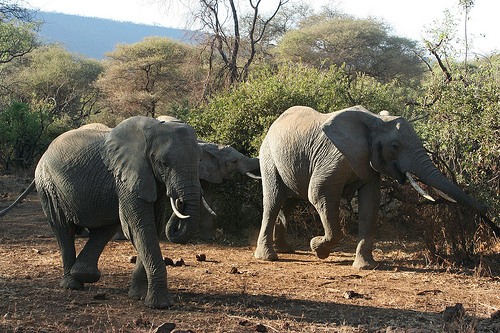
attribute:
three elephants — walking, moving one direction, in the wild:
[0, 104, 482, 310]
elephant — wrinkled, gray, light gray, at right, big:
[254, 105, 481, 270]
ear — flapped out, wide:
[319, 109, 384, 182]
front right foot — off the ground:
[306, 159, 349, 260]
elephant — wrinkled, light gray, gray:
[0, 115, 217, 308]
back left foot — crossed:
[70, 225, 118, 283]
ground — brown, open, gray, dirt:
[0, 239, 499, 333]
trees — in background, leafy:
[0, 0, 499, 243]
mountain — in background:
[0, 6, 233, 59]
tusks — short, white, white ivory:
[169, 196, 217, 218]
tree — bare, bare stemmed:
[182, 1, 288, 89]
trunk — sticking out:
[405, 142, 487, 216]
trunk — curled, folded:
[164, 171, 203, 243]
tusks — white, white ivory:
[405, 171, 458, 203]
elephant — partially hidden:
[197, 144, 260, 240]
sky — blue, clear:
[0, 0, 499, 63]